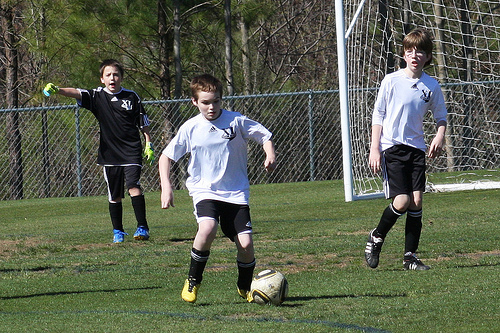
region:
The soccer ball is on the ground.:
[236, 246, 321, 311]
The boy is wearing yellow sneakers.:
[167, 259, 216, 303]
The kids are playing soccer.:
[21, 28, 449, 293]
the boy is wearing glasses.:
[383, 41, 456, 61]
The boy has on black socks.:
[182, 242, 218, 292]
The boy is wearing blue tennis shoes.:
[93, 216, 193, 258]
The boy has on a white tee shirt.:
[153, 106, 285, 213]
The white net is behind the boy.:
[331, 24, 496, 189]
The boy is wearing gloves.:
[35, 67, 80, 111]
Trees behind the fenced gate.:
[74, 9, 367, 153]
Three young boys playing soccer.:
[12, 14, 471, 316]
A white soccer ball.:
[247, 259, 293, 318]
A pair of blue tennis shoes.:
[97, 221, 155, 247]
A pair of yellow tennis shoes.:
[175, 269, 255, 306]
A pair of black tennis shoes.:
[364, 226, 429, 274]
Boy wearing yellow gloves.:
[33, 77, 159, 166]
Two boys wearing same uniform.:
[141, 17, 452, 294]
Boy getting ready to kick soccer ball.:
[155, 63, 289, 320]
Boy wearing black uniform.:
[43, 47, 156, 252]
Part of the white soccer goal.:
[329, 7, 494, 207]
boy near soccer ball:
[155, 73, 312, 316]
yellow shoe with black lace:
[169, 261, 220, 311]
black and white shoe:
[347, 224, 404, 289]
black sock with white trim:
[370, 190, 408, 282]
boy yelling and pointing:
[29, 53, 166, 249]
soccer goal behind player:
[317, 7, 487, 291]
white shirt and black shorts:
[349, 54, 464, 256]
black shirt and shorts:
[74, 81, 171, 228]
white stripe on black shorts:
[88, 154, 183, 218]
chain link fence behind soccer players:
[19, 76, 347, 206]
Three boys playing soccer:
[59, 50, 458, 316]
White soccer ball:
[249, 261, 296, 302]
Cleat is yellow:
[176, 275, 204, 302]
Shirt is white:
[173, 117, 270, 206]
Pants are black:
[385, 140, 434, 198]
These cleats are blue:
[106, 227, 161, 246]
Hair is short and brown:
[183, 68, 231, 105]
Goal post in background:
[325, 6, 365, 206]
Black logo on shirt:
[220, 120, 242, 145]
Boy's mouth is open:
[101, 74, 123, 86]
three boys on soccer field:
[68, 29, 453, 311]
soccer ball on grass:
[241, 262, 297, 311]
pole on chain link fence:
[12, 103, 69, 172]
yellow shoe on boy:
[172, 271, 214, 311]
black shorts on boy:
[189, 190, 261, 240]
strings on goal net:
[452, 10, 492, 133]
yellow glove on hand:
[138, 131, 163, 171]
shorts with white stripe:
[94, 160, 139, 202]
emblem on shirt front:
[218, 121, 243, 148]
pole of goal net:
[322, 81, 362, 200]